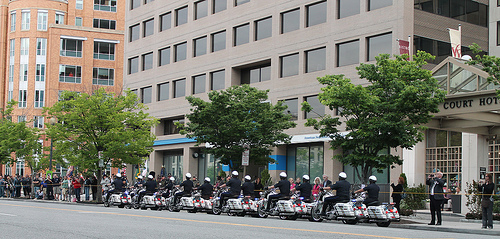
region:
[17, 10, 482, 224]
Picture taken outside.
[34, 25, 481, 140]
Picture taken during the day.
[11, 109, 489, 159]
Trees line the street.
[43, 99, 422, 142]
The trees are full of leaves.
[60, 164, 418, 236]
A procession of police officers.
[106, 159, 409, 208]
The police officers are riding motorcycles.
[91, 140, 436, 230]
The motorcycles are black and white.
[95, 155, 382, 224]
All of the officers are wearing helmets.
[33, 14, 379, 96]
Buildings in the background.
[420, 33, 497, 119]
The building says Court House.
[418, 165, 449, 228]
a man on the sidewalk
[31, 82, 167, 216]
a green tree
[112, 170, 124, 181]
a white helmet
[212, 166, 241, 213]
a man on the motorcycle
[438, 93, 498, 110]
black letters on the building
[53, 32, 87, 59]
the windows of a building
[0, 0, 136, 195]
an orange brick building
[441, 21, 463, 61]
a white banner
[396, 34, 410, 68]
a red banner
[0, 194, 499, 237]
a gray asphalt street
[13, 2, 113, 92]
this is a building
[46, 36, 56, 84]
the building is brown in color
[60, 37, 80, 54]
this is the window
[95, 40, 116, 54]
the window is closed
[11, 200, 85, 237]
this is the road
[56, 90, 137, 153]
this is a tree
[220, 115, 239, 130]
the tree has green leaves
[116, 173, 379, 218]
these are motorists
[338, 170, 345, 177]
this is a helmet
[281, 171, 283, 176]
the helmet is white in color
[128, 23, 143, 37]
a widow on a building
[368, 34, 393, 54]
a widow on a building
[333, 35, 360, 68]
a widow on a building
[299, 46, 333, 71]
a widow on a building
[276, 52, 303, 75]
a widow on a building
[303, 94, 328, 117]
a widow on a building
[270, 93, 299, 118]
a widow on a building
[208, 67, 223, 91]
a widow on a building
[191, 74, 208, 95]
a widow on a building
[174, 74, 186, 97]
a widow on a building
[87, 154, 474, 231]
There are many motorcycles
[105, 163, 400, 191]
The people are wearing helmets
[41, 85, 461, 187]
The trees are green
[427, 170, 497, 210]
People are taking photos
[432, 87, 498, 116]
This is the court house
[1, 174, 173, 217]
People line the streets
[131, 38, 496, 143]
There are many windows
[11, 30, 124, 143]
This building is brick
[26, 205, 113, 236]
The road has lines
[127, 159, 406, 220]
The people are wearing black